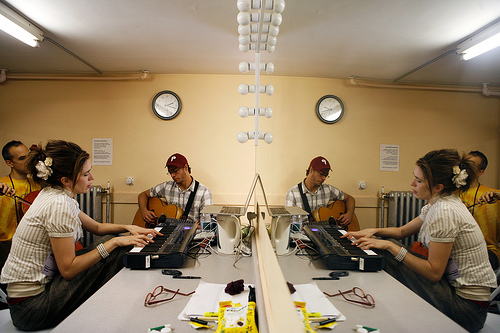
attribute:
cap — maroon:
[161, 153, 196, 174]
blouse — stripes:
[4, 186, 73, 281]